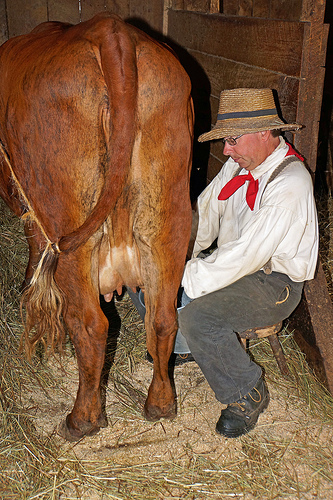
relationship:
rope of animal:
[18, 17, 138, 370] [0, 11, 196, 444]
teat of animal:
[99, 271, 143, 307] [0, 11, 196, 444]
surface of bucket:
[130, 293, 201, 366] [135, 286, 210, 364]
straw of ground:
[53, 432, 164, 497] [2, 420, 321, 480]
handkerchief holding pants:
[216, 158, 258, 211] [125, 247, 304, 405]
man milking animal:
[147, 87, 315, 438] [0, 11, 196, 444]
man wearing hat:
[147, 87, 315, 438] [197, 86, 304, 143]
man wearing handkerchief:
[147, 87, 315, 438] [213, 141, 305, 208]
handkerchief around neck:
[213, 141, 305, 208] [245, 136, 284, 174]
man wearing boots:
[147, 87, 315, 438] [147, 341, 274, 436]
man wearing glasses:
[147, 87, 315, 438] [222, 133, 239, 145]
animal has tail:
[0, 11, 196, 444] [16, 23, 137, 365]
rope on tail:
[0, 142, 61, 284] [16, 23, 137, 365]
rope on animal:
[0, 142, 61, 284] [0, 11, 196, 444]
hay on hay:
[0, 169, 331, 497] [0, 169, 331, 497]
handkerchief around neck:
[216, 158, 258, 211] [245, 136, 283, 171]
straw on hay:
[53, 432, 164, 497] [0, 169, 331, 497]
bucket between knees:
[139, 287, 194, 353] [125, 285, 233, 344]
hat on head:
[197, 86, 301, 141] [222, 129, 280, 169]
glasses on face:
[222, 133, 239, 145] [221, 136, 266, 169]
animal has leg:
[1, 11, 193, 441] [36, 204, 108, 440]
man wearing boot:
[177, 87, 319, 438] [215, 374, 270, 438]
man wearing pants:
[177, 87, 319, 438] [125, 247, 303, 402]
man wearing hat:
[177, 87, 319, 438] [197, 86, 301, 141]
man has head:
[177, 87, 319, 438] [222, 129, 280, 169]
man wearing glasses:
[177, 87, 319, 438] [222, 133, 245, 145]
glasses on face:
[222, 133, 245, 145] [223, 131, 267, 168]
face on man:
[223, 131, 267, 168] [177, 87, 319, 438]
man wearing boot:
[177, 87, 319, 438] [146, 348, 194, 366]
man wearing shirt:
[177, 87, 319, 438] [181, 135, 318, 298]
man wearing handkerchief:
[177, 87, 319, 438] [216, 158, 258, 211]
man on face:
[177, 87, 319, 438] [223, 131, 268, 171]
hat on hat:
[197, 86, 304, 143] [197, 86, 304, 143]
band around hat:
[213, 105, 283, 121] [197, 86, 304, 143]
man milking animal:
[177, 87, 319, 438] [0, 11, 196, 444]